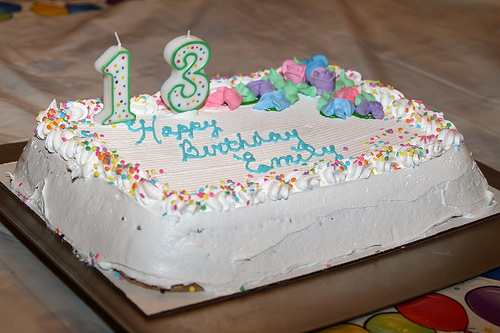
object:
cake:
[0, 26, 499, 293]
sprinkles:
[91, 145, 164, 195]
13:
[94, 30, 211, 125]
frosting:
[7, 134, 499, 298]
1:
[93, 30, 135, 125]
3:
[160, 30, 212, 114]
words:
[125, 111, 348, 173]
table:
[2, 0, 500, 333]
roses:
[206, 53, 386, 120]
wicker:
[114, 31, 121, 47]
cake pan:
[1, 141, 500, 333]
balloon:
[393, 294, 469, 332]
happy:
[125, 115, 223, 146]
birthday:
[179, 129, 308, 161]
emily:
[232, 142, 344, 175]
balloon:
[364, 312, 435, 333]